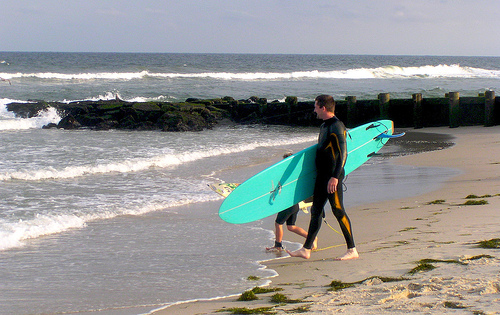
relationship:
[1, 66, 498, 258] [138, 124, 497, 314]
waves are on beach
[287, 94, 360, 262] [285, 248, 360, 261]
man has feet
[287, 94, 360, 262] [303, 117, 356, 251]
man wearing wet suit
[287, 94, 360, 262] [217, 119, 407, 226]
man holding surfboard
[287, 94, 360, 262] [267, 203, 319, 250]
man beside child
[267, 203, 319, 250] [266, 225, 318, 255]
child has legs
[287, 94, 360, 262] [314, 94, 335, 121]
man has head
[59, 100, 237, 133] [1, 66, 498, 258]
rocks are in waves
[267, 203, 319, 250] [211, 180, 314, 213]
child holding surfboard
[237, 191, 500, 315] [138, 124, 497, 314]
seaweed on beach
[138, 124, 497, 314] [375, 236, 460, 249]
beach has tracks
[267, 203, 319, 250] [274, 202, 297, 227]
child wearing shorts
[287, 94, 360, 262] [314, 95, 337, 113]
man has hair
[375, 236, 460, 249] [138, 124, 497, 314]
tracks are in beach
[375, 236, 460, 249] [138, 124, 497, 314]
tracks are on beach